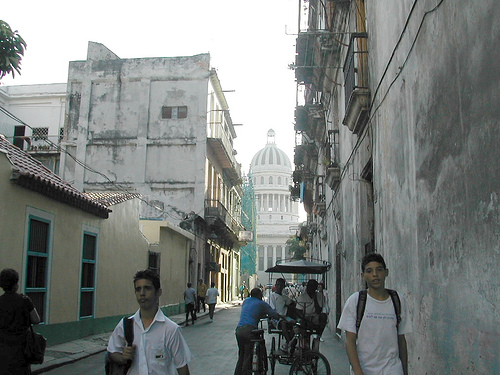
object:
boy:
[105, 269, 193, 375]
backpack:
[121, 316, 135, 346]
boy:
[337, 252, 408, 375]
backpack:
[355, 288, 403, 338]